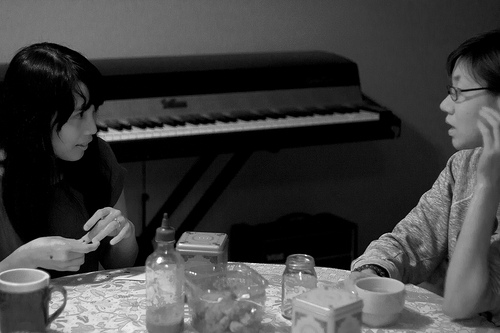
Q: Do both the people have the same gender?
A: Yes, all the people are female.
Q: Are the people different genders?
A: No, all the people are female.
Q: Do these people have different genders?
A: No, all the people are female.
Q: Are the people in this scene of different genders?
A: No, all the people are female.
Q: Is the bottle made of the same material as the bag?
A: Yes, both the bottle and the bag are made of plastic.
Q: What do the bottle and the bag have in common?
A: The material, both the bottle and the bag are plastic.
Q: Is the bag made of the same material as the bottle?
A: Yes, both the bag and the bottle are made of plastic.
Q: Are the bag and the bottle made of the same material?
A: Yes, both the bag and the bottle are made of plastic.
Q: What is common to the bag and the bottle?
A: The material, both the bag and the bottle are plastic.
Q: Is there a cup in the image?
A: Yes, there is a cup.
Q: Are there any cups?
A: Yes, there is a cup.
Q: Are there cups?
A: Yes, there is a cup.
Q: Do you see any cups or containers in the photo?
A: Yes, there is a cup.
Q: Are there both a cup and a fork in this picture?
A: No, there is a cup but no forks.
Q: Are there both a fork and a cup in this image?
A: No, there is a cup but no forks.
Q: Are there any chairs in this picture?
A: No, there are no chairs.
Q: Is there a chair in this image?
A: No, there are no chairs.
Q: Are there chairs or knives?
A: No, there are no chairs or knives.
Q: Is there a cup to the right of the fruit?
A: Yes, there is a cup to the right of the fruit.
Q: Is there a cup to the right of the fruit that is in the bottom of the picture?
A: Yes, there is a cup to the right of the fruit.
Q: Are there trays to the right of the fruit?
A: No, there is a cup to the right of the fruit.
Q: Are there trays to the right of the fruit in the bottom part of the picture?
A: No, there is a cup to the right of the fruit.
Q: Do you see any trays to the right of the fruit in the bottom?
A: No, there is a cup to the right of the fruit.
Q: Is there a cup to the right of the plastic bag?
A: Yes, there is a cup to the right of the bag.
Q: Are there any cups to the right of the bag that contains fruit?
A: Yes, there is a cup to the right of the bag.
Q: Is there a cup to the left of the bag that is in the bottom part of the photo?
A: No, the cup is to the right of the bag.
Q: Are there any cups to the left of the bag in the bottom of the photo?
A: No, the cup is to the right of the bag.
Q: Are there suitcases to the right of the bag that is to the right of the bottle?
A: No, there is a cup to the right of the bag.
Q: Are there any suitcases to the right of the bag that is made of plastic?
A: No, there is a cup to the right of the bag.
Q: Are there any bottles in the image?
A: Yes, there is a bottle.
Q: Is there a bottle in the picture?
A: Yes, there is a bottle.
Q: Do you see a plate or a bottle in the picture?
A: Yes, there is a bottle.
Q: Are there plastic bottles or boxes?
A: Yes, there is a plastic bottle.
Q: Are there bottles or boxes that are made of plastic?
A: Yes, the bottle is made of plastic.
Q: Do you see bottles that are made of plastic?
A: Yes, there is a bottle that is made of plastic.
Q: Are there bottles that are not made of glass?
A: Yes, there is a bottle that is made of plastic.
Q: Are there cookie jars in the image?
A: No, there are no cookie jars.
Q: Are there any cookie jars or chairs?
A: No, there are no cookie jars or chairs.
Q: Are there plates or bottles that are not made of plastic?
A: No, there is a bottle but it is made of plastic.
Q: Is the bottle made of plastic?
A: Yes, the bottle is made of plastic.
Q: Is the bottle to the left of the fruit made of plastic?
A: Yes, the bottle is made of plastic.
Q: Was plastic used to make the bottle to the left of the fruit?
A: Yes, the bottle is made of plastic.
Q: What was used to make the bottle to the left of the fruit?
A: The bottle is made of plastic.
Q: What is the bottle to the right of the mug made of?
A: The bottle is made of plastic.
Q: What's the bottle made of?
A: The bottle is made of plastic.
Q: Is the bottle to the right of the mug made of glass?
A: No, the bottle is made of plastic.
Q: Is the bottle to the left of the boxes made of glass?
A: No, the bottle is made of plastic.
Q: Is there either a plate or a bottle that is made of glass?
A: No, there is a bottle but it is made of plastic.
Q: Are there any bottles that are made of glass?
A: No, there is a bottle but it is made of plastic.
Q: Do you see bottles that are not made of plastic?
A: No, there is a bottle but it is made of plastic.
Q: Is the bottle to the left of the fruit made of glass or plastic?
A: The bottle is made of plastic.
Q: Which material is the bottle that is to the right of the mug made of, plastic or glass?
A: The bottle is made of plastic.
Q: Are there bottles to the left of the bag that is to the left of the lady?
A: Yes, there is a bottle to the left of the bag.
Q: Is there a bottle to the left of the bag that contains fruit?
A: Yes, there is a bottle to the left of the bag.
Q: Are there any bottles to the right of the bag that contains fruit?
A: No, the bottle is to the left of the bag.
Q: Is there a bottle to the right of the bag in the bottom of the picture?
A: No, the bottle is to the left of the bag.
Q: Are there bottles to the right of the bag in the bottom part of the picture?
A: No, the bottle is to the left of the bag.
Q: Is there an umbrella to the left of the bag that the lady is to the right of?
A: No, there is a bottle to the left of the bag.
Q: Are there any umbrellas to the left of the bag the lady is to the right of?
A: No, there is a bottle to the left of the bag.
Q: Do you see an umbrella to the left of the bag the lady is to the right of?
A: No, there is a bottle to the left of the bag.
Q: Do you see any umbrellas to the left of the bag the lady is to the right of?
A: No, there is a bottle to the left of the bag.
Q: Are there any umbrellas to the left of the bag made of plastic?
A: No, there is a bottle to the left of the bag.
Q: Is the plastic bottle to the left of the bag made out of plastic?
A: Yes, the bottle is to the left of the bag.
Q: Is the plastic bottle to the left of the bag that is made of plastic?
A: Yes, the bottle is to the left of the bag.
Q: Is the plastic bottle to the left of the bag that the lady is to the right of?
A: Yes, the bottle is to the left of the bag.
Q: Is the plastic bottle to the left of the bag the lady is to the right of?
A: Yes, the bottle is to the left of the bag.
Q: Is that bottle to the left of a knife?
A: No, the bottle is to the left of the bag.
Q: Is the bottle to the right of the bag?
A: No, the bottle is to the left of the bag.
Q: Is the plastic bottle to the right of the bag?
A: No, the bottle is to the left of the bag.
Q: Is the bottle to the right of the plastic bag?
A: No, the bottle is to the left of the bag.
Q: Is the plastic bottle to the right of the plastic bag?
A: No, the bottle is to the left of the bag.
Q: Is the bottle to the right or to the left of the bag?
A: The bottle is to the left of the bag.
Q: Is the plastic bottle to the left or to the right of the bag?
A: The bottle is to the left of the bag.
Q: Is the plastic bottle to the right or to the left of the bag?
A: The bottle is to the left of the bag.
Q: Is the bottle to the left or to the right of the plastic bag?
A: The bottle is to the left of the bag.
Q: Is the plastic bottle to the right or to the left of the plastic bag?
A: The bottle is to the left of the bag.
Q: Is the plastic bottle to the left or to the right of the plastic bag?
A: The bottle is to the left of the bag.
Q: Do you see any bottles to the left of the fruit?
A: Yes, there is a bottle to the left of the fruit.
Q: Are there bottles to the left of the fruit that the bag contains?
A: Yes, there is a bottle to the left of the fruit.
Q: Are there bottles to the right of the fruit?
A: No, the bottle is to the left of the fruit.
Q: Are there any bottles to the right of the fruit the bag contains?
A: No, the bottle is to the left of the fruit.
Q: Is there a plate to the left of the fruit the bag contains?
A: No, there is a bottle to the left of the fruit.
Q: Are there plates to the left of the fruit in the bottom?
A: No, there is a bottle to the left of the fruit.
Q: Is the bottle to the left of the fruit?
A: Yes, the bottle is to the left of the fruit.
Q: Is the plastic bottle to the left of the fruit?
A: Yes, the bottle is to the left of the fruit.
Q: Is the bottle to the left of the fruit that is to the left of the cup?
A: Yes, the bottle is to the left of the fruit.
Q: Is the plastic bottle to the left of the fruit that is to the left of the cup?
A: Yes, the bottle is to the left of the fruit.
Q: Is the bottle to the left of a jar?
A: No, the bottle is to the left of the fruit.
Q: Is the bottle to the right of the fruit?
A: No, the bottle is to the left of the fruit.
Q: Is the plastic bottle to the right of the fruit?
A: No, the bottle is to the left of the fruit.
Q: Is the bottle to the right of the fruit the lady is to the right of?
A: No, the bottle is to the left of the fruit.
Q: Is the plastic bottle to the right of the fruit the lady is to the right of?
A: No, the bottle is to the left of the fruit.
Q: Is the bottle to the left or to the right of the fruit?
A: The bottle is to the left of the fruit.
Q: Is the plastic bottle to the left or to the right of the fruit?
A: The bottle is to the left of the fruit.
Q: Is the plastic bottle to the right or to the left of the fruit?
A: The bottle is to the left of the fruit.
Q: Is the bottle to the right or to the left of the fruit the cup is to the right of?
A: The bottle is to the left of the fruit.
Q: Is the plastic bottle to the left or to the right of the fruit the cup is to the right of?
A: The bottle is to the left of the fruit.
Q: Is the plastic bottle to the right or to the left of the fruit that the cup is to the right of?
A: The bottle is to the left of the fruit.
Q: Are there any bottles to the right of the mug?
A: Yes, there is a bottle to the right of the mug.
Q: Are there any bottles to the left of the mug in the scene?
A: No, the bottle is to the right of the mug.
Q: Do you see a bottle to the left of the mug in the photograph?
A: No, the bottle is to the right of the mug.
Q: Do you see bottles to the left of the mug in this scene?
A: No, the bottle is to the right of the mug.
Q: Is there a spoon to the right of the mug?
A: No, there is a bottle to the right of the mug.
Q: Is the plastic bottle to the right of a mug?
A: Yes, the bottle is to the right of a mug.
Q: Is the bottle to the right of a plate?
A: No, the bottle is to the right of a mug.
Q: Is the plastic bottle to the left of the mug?
A: No, the bottle is to the right of the mug.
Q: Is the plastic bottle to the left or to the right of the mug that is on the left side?
A: The bottle is to the right of the mug.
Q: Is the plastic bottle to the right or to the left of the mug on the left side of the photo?
A: The bottle is to the right of the mug.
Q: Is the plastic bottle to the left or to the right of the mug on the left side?
A: The bottle is to the right of the mug.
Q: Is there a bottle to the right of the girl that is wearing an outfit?
A: Yes, there is a bottle to the right of the girl.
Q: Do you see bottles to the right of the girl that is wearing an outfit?
A: Yes, there is a bottle to the right of the girl.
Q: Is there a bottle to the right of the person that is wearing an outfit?
A: Yes, there is a bottle to the right of the girl.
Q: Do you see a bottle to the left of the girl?
A: No, the bottle is to the right of the girl.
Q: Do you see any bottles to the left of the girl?
A: No, the bottle is to the right of the girl.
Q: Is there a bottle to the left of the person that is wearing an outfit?
A: No, the bottle is to the right of the girl.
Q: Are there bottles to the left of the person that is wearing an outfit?
A: No, the bottle is to the right of the girl.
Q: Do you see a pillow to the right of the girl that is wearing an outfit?
A: No, there is a bottle to the right of the girl.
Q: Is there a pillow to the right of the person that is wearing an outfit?
A: No, there is a bottle to the right of the girl.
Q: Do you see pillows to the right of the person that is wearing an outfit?
A: No, there is a bottle to the right of the girl.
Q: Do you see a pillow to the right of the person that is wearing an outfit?
A: No, there is a bottle to the right of the girl.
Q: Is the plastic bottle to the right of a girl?
A: Yes, the bottle is to the right of a girl.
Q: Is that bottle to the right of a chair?
A: No, the bottle is to the right of a girl.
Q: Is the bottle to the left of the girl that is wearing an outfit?
A: No, the bottle is to the right of the girl.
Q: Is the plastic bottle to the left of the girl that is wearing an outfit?
A: No, the bottle is to the right of the girl.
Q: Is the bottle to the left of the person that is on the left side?
A: No, the bottle is to the right of the girl.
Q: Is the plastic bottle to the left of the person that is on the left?
A: No, the bottle is to the right of the girl.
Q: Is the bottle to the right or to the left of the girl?
A: The bottle is to the right of the girl.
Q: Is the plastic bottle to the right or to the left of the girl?
A: The bottle is to the right of the girl.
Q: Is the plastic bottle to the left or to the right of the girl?
A: The bottle is to the right of the girl.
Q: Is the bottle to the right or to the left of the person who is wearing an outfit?
A: The bottle is to the right of the girl.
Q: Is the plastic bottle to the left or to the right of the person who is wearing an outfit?
A: The bottle is to the right of the girl.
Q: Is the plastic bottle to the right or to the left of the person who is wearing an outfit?
A: The bottle is to the right of the girl.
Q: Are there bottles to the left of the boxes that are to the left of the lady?
A: Yes, there is a bottle to the left of the boxes.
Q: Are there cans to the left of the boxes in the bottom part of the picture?
A: No, there is a bottle to the left of the boxes.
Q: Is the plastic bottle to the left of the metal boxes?
A: Yes, the bottle is to the left of the boxes.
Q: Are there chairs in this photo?
A: No, there are no chairs.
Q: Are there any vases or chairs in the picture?
A: No, there are no chairs or vases.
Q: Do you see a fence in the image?
A: No, there are no fences.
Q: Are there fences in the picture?
A: No, there are no fences.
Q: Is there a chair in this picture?
A: No, there are no chairs.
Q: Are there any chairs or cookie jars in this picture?
A: No, there are no chairs or cookie jars.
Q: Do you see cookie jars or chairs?
A: No, there are no chairs or cookie jars.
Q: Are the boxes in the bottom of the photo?
A: Yes, the boxes are in the bottom of the image.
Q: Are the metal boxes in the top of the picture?
A: No, the boxes are in the bottom of the image.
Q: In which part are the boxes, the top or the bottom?
A: The boxes are in the bottom of the image.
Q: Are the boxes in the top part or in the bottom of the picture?
A: The boxes are in the bottom of the image.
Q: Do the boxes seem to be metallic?
A: Yes, the boxes are metallic.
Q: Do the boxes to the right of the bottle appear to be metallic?
A: Yes, the boxes are metallic.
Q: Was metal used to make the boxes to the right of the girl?
A: Yes, the boxes are made of metal.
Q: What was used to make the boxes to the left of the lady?
A: The boxes are made of metal.